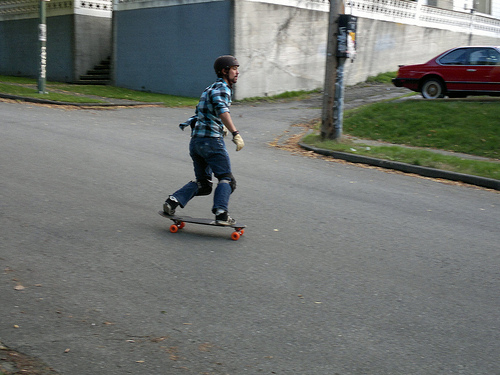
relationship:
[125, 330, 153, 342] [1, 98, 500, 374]
crack in road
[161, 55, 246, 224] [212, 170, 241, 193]
man wearing a kneepad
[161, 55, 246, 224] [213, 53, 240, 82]
man wearing a helmet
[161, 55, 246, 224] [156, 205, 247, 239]
man on a skateboard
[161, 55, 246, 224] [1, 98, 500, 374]
man riding in road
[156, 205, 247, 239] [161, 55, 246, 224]
skateboard under man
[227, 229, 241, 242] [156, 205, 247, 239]
wheel on skateboard